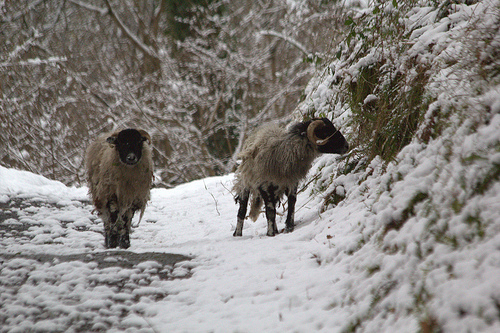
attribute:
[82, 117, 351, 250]
sheep — black, white, walking, dry, shaggy, standing, strolling, lookig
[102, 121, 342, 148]
horns — brown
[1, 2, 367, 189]
branches — icy, snowy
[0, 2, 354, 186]
trees — snowy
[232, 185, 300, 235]
legs — black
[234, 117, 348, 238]
ram — looking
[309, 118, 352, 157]
fur — black, shagg